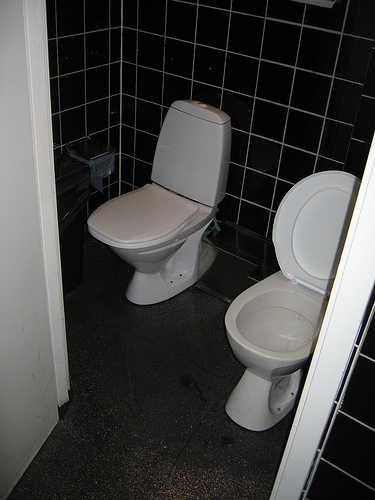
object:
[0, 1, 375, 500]
bathroom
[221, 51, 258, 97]
tile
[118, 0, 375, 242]
wall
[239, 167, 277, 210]
tile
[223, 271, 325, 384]
seat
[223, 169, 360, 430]
toilet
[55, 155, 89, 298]
can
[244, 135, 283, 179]
tile